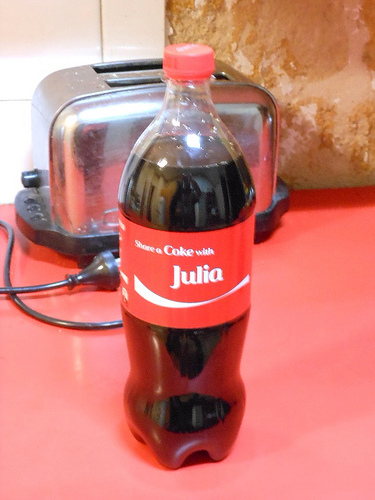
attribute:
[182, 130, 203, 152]
light — shining off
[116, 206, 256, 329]
sticker — red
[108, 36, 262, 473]
bottle — Coke's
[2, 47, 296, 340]
toaster — silver and black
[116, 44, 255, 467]
bottle — clear, plastic, for soda, Coke's, of Coke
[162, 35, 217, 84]
top — red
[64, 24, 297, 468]
bottle — coke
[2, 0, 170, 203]
tiles — white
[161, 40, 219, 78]
bottle cap — red, for bottle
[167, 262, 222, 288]
name — Julia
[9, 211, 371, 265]
counter top — red colored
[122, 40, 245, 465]
bottle — full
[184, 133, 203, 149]
glare — from light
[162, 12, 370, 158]
wall — brown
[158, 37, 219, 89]
lid — red, plastic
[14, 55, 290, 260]
toaster — chrome, electrical 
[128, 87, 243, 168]
drops — Coke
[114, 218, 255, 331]
label — red and white, personalized